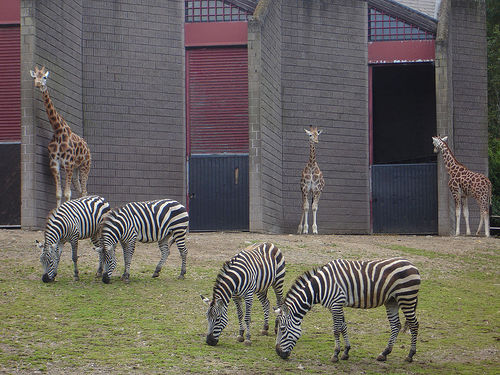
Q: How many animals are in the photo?
A: Seven.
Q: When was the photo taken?
A: Daytime.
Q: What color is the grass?
A: Green.